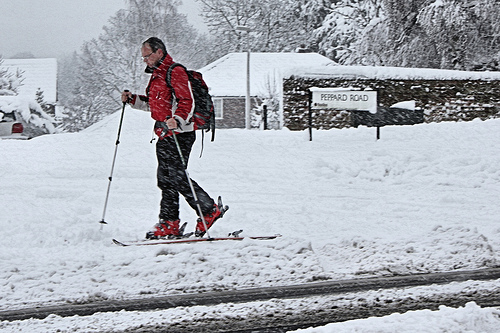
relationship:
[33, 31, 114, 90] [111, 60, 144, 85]
wind blowing snow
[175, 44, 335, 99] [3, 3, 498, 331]
roof covered with snow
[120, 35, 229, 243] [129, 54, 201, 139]
man wearing jacket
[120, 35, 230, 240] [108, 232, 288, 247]
man wearing skis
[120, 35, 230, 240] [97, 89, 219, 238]
man holding ski poles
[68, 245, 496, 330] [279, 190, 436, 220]
tracks in snow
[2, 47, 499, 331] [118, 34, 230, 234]
snow falling on a cross country skier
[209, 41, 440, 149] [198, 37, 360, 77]
house with a snow covered roof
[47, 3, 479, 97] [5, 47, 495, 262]
trees covered in snow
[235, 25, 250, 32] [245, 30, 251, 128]
light on pole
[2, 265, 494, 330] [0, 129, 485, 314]
cement road underneath snow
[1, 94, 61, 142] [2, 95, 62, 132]
car parked with snow